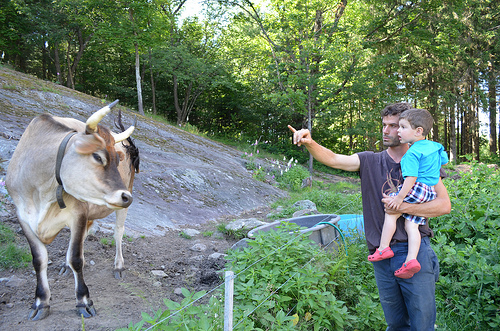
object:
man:
[286, 103, 451, 331]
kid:
[366, 107, 448, 279]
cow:
[6, 99, 140, 321]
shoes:
[367, 247, 421, 280]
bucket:
[245, 213, 345, 259]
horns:
[83, 98, 136, 143]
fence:
[160, 193, 362, 321]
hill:
[0, 66, 312, 241]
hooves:
[27, 279, 96, 318]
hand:
[287, 124, 311, 147]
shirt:
[399, 140, 448, 187]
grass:
[231, 140, 363, 220]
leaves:
[0, 0, 500, 156]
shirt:
[354, 149, 434, 252]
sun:
[169, 9, 278, 84]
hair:
[397, 107, 433, 136]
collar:
[54, 130, 78, 209]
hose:
[312, 221, 352, 301]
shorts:
[388, 181, 439, 226]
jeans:
[369, 236, 440, 331]